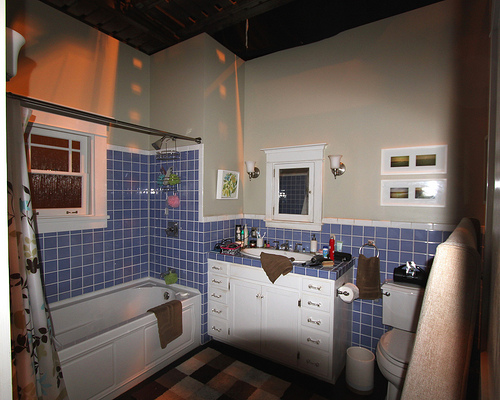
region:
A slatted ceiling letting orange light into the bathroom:
[15, 11, 289, 111]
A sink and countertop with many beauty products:
[208, 217, 349, 381]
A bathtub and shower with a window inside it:
[16, 112, 189, 351]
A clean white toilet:
[368, 260, 447, 388]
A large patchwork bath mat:
[141, 324, 285, 399]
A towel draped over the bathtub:
[136, 298, 195, 348]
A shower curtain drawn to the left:
[8, 102, 77, 395]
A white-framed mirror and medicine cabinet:
[258, 142, 326, 233]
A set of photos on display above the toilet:
[369, 137, 449, 211]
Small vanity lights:
[236, 150, 351, 185]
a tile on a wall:
[42, 237, 57, 249]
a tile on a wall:
[56, 233, 70, 248]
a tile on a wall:
[46, 248, 59, 258]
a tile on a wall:
[46, 259, 58, 271]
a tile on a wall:
[46, 271, 60, 288]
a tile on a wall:
[47, 282, 59, 300]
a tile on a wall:
[56, 244, 71, 261]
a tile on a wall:
[56, 257, 69, 268]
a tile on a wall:
[58, 272, 71, 282]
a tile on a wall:
[61, 282, 73, 291]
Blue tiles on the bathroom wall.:
[113, 200, 185, 277]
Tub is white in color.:
[107, 297, 177, 377]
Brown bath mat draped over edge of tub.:
[142, 312, 201, 357]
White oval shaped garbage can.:
[346, 334, 371, 392]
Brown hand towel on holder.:
[358, 250, 378, 341]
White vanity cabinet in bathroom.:
[219, 276, 362, 395]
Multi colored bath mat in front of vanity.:
[190, 368, 225, 393]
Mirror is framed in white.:
[267, 142, 343, 272]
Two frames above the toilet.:
[376, 146, 451, 239]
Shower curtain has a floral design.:
[18, 282, 98, 395]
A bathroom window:
[29, 113, 98, 217]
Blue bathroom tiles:
[118, 161, 156, 278]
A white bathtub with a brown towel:
[55, 270, 206, 383]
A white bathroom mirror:
[260, 150, 323, 223]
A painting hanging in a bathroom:
[210, 155, 365, 316]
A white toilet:
[367, 270, 447, 390]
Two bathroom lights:
[221, 136, 367, 233]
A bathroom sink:
[200, 213, 361, 309]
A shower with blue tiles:
[130, 111, 207, 377]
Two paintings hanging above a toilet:
[373, 137, 465, 389]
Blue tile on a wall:
[109, 170, 210, 265]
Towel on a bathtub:
[113, 293, 221, 378]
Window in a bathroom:
[28, 126, 117, 247]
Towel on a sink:
[251, 225, 311, 288]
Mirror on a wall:
[259, 137, 337, 227]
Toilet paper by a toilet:
[328, 281, 364, 298]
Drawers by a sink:
[199, 255, 238, 350]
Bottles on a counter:
[233, 207, 378, 276]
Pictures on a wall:
[364, 146, 476, 230]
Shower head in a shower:
[146, 128, 198, 161]